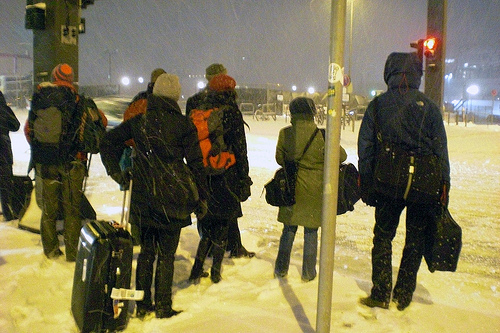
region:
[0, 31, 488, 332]
People waiting on the snow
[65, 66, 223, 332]
Woman with a suitcase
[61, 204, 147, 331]
Suitcase is black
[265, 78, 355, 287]
Woman wears a green coat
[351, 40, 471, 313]
Man wears a balck coat with hood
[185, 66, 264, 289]
Woman carry a backpack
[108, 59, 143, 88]
Lights in the background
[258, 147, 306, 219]
Black handbag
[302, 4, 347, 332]
Pole of light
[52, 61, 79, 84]
Cap is orange and grey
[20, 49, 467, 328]
people waiting for ground transportation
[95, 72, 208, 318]
woman who is dressed for the cold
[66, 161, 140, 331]
luggage at rest in the snow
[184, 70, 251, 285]
a woman with a backpack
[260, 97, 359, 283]
a woman carrying two bags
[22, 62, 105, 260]
a man with a backpack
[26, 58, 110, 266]
a man with a sock hat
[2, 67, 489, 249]
a brightly lighted area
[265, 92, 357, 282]
woman wearing a green coat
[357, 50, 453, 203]
jacket with a built in hood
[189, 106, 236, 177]
Red and black backpack on man's back.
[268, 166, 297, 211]
Black handbag on woman's side.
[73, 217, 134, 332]
Large suitcase being rolled behind woman.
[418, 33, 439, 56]
Red city streetlight on street.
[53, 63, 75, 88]
Orange hat on man's head.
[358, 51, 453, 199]
Blue jacket on a man.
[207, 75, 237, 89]
Red hat on woman's head.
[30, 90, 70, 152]
Green backpack on man's back.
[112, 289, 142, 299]
Airline baggage tag on bag.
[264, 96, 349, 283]
Pedestrian waiting for street light to change.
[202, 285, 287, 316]
white snow on the ground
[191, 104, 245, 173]
orange and black back pack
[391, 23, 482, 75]
bright light on post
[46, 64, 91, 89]
orange and brown wool cap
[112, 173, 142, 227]
tall handle on suitcase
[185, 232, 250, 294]
tall black leather boots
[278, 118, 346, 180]
luggage strap over woman's back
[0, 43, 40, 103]
small building in the fore ground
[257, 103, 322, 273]
woman wearing green coat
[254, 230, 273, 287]
lines in the white snow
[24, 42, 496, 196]
people standing in the snow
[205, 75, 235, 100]
red hat on a woman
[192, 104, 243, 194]
orange and gray backpack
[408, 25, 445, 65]
red light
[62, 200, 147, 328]
large black suitcase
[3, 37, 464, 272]
passengers awaiting their ride arrival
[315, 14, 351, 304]
a pole with stickers on it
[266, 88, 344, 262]
woman in green coat wearing a sling bag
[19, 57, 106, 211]
man with orange and grey striped hat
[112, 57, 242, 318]
person in black